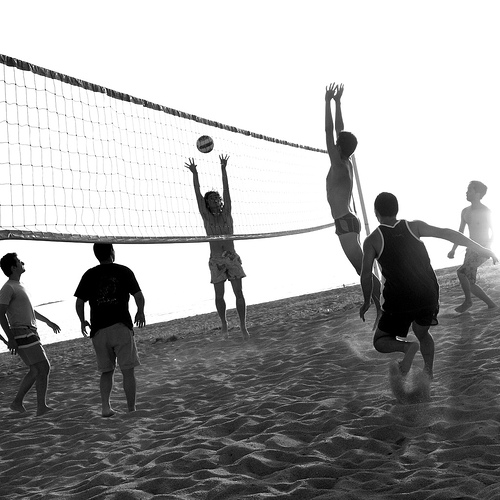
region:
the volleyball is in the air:
[186, 113, 263, 163]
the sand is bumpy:
[238, 400, 341, 470]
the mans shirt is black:
[389, 248, 418, 296]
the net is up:
[63, 133, 170, 205]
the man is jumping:
[168, 165, 270, 318]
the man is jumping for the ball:
[179, 125, 261, 397]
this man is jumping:
[306, 64, 376, 326]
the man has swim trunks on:
[186, 235, 262, 315]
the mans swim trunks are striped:
[0, 308, 51, 374]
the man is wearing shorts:
[320, 202, 369, 244]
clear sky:
[128, 18, 269, 88]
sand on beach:
[180, 399, 323, 478]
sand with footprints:
[143, 421, 308, 487]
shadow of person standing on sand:
[376, 365, 417, 479]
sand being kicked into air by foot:
[386, 358, 431, 397]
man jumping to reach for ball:
[171, 131, 257, 336]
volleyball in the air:
[188, 133, 224, 151]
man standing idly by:
[74, 238, 147, 418]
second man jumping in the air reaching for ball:
[323, 73, 383, 319]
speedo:
[329, 215, 360, 235]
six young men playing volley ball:
[0, 131, 486, 427]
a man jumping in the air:
[186, 144, 241, 359]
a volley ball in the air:
[192, 121, 218, 162]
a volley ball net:
[50, 79, 333, 255]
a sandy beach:
[124, 381, 339, 498]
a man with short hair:
[370, 167, 430, 227]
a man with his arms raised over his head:
[308, 70, 358, 256]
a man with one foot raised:
[383, 323, 425, 390]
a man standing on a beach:
[58, 223, 146, 424]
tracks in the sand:
[127, 366, 377, 472]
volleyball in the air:
[197, 133, 214, 153]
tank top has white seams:
[368, 219, 436, 299]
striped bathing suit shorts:
[10, 328, 45, 363]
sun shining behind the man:
[483, 207, 498, 244]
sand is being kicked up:
[388, 362, 425, 400]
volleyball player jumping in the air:
[185, 154, 252, 353]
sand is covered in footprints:
[5, 269, 496, 496]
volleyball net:
[0, 55, 375, 252]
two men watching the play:
[0, 239, 145, 409]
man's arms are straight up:
[322, 82, 346, 165]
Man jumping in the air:
[179, 155, 256, 344]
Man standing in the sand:
[71, 238, 154, 425]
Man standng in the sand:
[0, 248, 59, 415]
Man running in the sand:
[349, 192, 499, 384]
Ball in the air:
[185, 123, 235, 155]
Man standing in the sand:
[445, 175, 499, 313]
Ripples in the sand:
[149, 352, 499, 499]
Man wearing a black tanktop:
[358, 217, 443, 314]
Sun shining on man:
[423, 169, 498, 320]